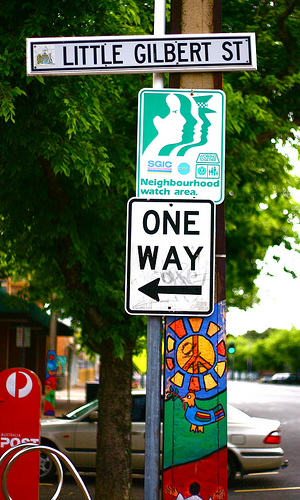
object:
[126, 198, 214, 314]
graffitti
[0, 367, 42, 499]
sign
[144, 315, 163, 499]
pole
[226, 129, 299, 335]
sky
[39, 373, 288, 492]
car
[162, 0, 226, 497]
pole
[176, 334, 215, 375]
sign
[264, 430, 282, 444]
light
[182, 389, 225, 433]
bird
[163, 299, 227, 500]
graffiti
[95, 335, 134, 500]
trunk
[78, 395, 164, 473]
door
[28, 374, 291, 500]
parking spot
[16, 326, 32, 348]
sign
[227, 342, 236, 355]
light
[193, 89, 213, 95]
brim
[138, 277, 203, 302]
arrow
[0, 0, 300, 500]
tree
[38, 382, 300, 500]
street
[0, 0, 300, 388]
background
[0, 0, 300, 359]
leaf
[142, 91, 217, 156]
profile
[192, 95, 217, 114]
hat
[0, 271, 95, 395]
building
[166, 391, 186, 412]
branch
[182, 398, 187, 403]
mouth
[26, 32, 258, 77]
sign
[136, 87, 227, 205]
sign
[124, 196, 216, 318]
sign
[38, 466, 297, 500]
lot